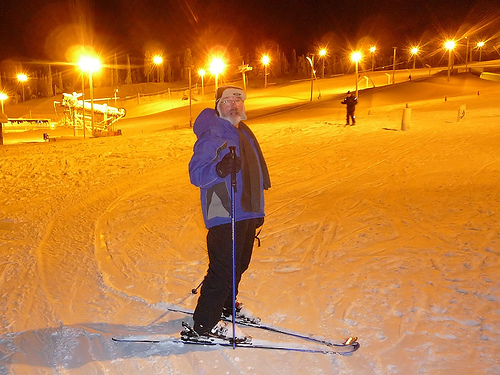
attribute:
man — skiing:
[183, 82, 275, 346]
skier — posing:
[183, 82, 275, 344]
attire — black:
[337, 99, 360, 114]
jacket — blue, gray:
[183, 106, 268, 231]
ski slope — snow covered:
[7, 75, 497, 370]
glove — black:
[219, 152, 242, 178]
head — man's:
[220, 89, 247, 121]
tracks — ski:
[189, 297, 280, 360]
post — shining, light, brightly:
[73, 40, 94, 102]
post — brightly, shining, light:
[55, 35, 113, 107]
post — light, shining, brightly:
[62, 46, 106, 112]